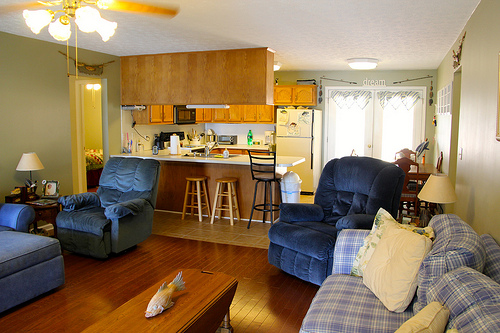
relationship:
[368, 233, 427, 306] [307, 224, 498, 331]
pillow on top of couch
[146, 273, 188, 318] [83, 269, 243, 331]
fish on top of table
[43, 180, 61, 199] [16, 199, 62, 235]
frame on top of table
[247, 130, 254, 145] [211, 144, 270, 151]
bottle on top of counter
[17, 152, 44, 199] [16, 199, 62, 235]
lamp on table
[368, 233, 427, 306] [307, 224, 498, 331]
pillow laying on couch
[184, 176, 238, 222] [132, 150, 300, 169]
stools under bar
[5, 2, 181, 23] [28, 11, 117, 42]
fan and fixture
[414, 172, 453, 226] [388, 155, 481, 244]
lamp in corner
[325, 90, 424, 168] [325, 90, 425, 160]
doors with doors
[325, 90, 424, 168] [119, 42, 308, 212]
doors next to kitchen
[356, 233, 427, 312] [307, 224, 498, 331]
pillow on top of couch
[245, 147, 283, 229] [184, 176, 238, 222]
stool next to stools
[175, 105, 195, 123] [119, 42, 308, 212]
microwave in kitchen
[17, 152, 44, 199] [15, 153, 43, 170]
lamp with shade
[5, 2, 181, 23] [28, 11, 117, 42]
fan with fixture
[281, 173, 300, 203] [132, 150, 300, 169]
can under bar